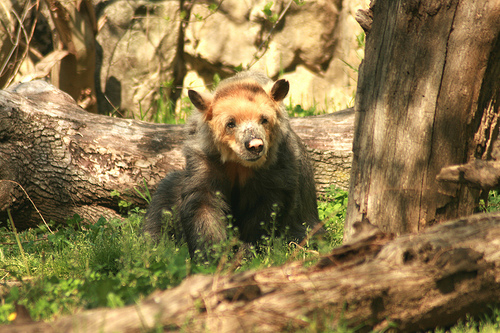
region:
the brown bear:
[145, 69, 328, 264]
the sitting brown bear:
[145, 67, 341, 265]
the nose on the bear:
[241, 137, 264, 154]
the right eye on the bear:
[220, 116, 236, 130]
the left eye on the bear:
[255, 112, 270, 128]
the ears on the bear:
[181, 74, 292, 111]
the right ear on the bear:
[182, 85, 210, 112]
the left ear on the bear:
[265, 81, 292, 101]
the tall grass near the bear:
[76, 204, 281, 285]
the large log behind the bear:
[10, 74, 377, 214]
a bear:
[137, 61, 292, 226]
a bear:
[138, 76, 338, 326]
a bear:
[225, 205, 296, 325]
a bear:
[94, 12, 312, 274]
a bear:
[220, 108, 330, 306]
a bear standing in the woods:
[138, 79, 323, 266]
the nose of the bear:
[243, 134, 263, 154]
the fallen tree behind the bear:
[4, 60, 359, 210]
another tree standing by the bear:
[341, 2, 475, 218]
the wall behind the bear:
[15, 4, 359, 116]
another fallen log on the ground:
[2, 197, 492, 329]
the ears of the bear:
[183, 76, 303, 102]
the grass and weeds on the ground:
[18, 222, 161, 310]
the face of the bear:
[209, 103, 289, 169]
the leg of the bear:
[153, 181, 240, 267]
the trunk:
[31, 85, 366, 262]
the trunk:
[32, 101, 202, 231]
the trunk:
[75, 70, 223, 204]